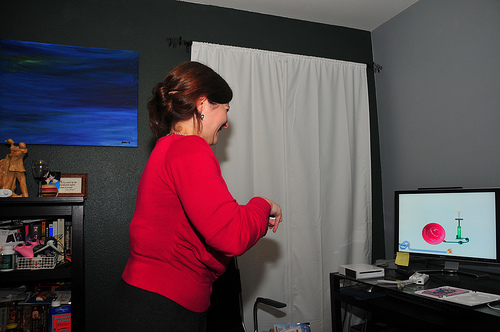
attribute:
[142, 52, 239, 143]
red hair — red 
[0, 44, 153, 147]
painting — blue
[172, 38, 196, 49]
curtain rod — black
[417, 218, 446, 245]
ball — pink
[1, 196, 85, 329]
bookshelf — wooden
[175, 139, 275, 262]
sleeves — LONG 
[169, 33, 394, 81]
curtain rod — black 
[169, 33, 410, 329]
curtain — WHITE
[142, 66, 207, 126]
hair — IN AN UPDO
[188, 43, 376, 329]
curtain — white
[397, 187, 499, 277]
television — small , black 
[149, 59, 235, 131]
hair — red 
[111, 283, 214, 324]
bottom — dark 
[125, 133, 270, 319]
shirt — Pink , red 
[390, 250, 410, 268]
note — yellow 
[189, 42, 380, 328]
drape — hanging 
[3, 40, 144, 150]
picture — Blue 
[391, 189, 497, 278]
monitor — black 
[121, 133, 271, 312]
sweater — pink 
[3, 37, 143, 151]
painting — blue 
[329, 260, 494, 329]
desk — black 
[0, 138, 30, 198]
sculpture — wood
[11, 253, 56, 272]
box — white, plastic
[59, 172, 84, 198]
frame — wooden